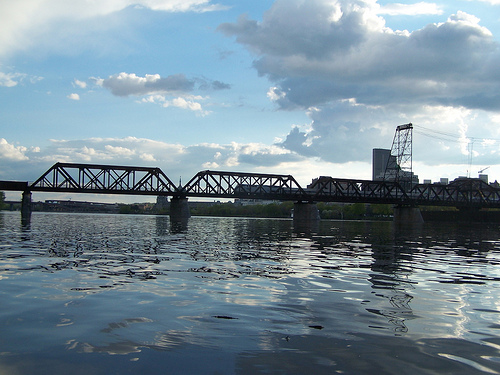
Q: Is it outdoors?
A: Yes, it is outdoors.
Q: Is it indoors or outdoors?
A: It is outdoors.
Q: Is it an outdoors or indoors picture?
A: It is outdoors.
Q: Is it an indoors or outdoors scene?
A: It is outdoors.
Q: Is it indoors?
A: No, it is outdoors.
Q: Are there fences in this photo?
A: No, there are no fences.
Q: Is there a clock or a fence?
A: No, there are no fences or clocks.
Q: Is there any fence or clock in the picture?
A: No, there are no fences or clocks.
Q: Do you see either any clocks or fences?
A: No, there are no fences or clocks.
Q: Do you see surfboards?
A: No, there are no surfboards.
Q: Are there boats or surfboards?
A: No, there are no surfboards or boats.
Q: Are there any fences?
A: No, there are no fences.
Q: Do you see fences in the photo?
A: No, there are no fences.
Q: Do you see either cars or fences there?
A: No, there are no fences or cars.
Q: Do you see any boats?
A: No, there are no boats.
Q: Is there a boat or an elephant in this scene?
A: No, there are no boats or elephants.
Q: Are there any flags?
A: No, there are no flags.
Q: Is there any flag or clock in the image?
A: No, there are no flags or clocks.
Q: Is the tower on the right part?
A: Yes, the tower is on the right of the image.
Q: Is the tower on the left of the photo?
A: No, the tower is on the right of the image.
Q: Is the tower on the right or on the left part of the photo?
A: The tower is on the right of the image.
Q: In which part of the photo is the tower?
A: The tower is on the right of the image.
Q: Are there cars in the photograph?
A: No, there are no cars.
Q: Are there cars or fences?
A: No, there are no cars or fences.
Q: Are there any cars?
A: No, there are no cars.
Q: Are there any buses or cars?
A: No, there are no cars or buses.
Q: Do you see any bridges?
A: Yes, there is a bridge.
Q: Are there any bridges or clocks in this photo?
A: Yes, there is a bridge.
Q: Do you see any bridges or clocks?
A: Yes, there is a bridge.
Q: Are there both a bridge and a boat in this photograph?
A: No, there is a bridge but no boats.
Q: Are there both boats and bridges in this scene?
A: No, there is a bridge but no boats.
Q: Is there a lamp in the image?
A: No, there are no lamps.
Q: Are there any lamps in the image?
A: No, there are no lamps.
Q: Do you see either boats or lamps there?
A: No, there are no lamps or boats.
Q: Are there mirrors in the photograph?
A: No, there are no mirrors.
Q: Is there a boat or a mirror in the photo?
A: No, there are no mirrors or boats.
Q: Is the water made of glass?
A: Yes, the water is made of glass.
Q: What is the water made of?
A: The water is made of glass.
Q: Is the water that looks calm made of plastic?
A: No, the water is made of glass.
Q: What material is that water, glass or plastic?
A: The water is made of glass.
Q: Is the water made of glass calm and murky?
A: Yes, the water is calm and murky.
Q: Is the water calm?
A: Yes, the water is calm.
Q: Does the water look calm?
A: Yes, the water is calm.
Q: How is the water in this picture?
A: The water is calm.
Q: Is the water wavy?
A: No, the water is calm.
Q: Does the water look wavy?
A: No, the water is calm.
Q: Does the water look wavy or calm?
A: The water is calm.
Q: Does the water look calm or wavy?
A: The water is calm.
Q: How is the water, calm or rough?
A: The water is calm.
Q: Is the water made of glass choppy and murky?
A: No, the water is murky but calm.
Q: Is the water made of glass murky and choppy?
A: No, the water is murky but calm.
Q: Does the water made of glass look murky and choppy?
A: No, the water is murky but calm.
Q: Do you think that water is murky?
A: Yes, the water is murky.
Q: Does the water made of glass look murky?
A: Yes, the water is murky.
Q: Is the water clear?
A: No, the water is murky.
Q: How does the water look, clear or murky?
A: The water is murky.